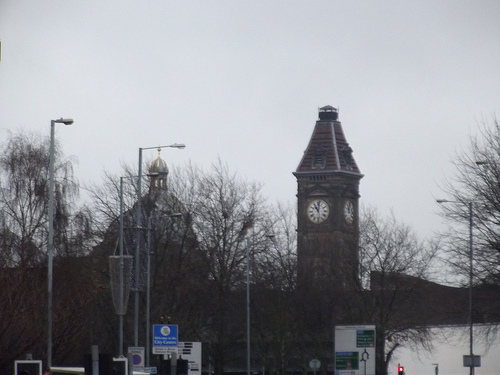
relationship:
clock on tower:
[307, 199, 331, 224] [292, 103, 364, 284]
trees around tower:
[0, 112, 499, 373] [292, 103, 364, 284]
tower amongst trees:
[292, 103, 364, 284] [0, 112, 499, 373]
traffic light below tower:
[396, 362, 405, 374] [292, 103, 364, 284]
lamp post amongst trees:
[436, 198, 475, 373] [0, 112, 499, 373]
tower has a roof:
[292, 103, 364, 284] [318, 102, 339, 120]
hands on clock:
[314, 200, 322, 214] [307, 199, 331, 224]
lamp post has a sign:
[436, 198, 475, 373] [462, 353, 481, 367]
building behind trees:
[1, 104, 387, 374] [0, 112, 499, 373]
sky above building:
[0, 0, 499, 372] [1, 104, 387, 374]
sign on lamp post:
[462, 353, 481, 367] [436, 198, 475, 373]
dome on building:
[91, 143, 200, 250] [1, 104, 387, 374]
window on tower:
[311, 143, 327, 171] [292, 103, 364, 284]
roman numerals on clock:
[309, 201, 329, 224] [307, 199, 331, 224]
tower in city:
[292, 103, 364, 284] [0, 1, 500, 373]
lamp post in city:
[436, 198, 475, 373] [0, 1, 500, 373]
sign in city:
[462, 353, 481, 367] [0, 1, 500, 373]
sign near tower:
[151, 323, 180, 355] [292, 103, 364, 284]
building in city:
[1, 104, 387, 374] [0, 1, 500, 373]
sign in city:
[151, 323, 180, 355] [0, 1, 500, 373]